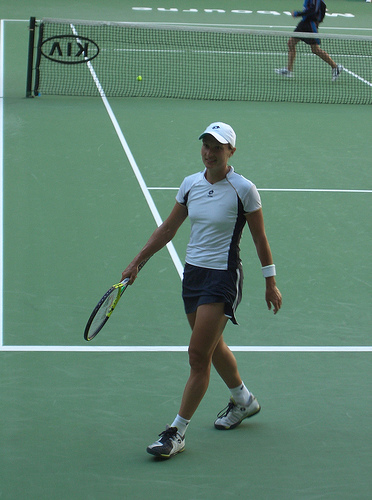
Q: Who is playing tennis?
A: Two people.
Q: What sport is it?
A: Tennis.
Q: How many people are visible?
A: Two.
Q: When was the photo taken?
A: Daytime.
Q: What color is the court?
A: Green.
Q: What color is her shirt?
A: White.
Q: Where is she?
A: Tennis court.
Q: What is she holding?
A: A tennis racket.